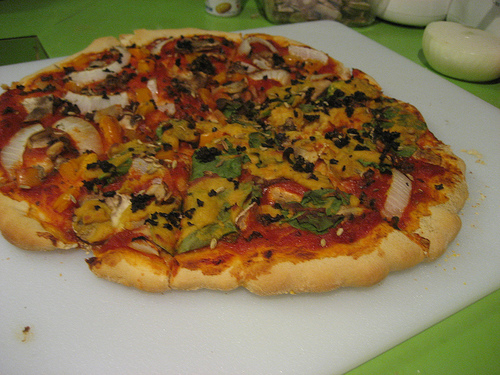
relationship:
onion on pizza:
[381, 167, 414, 222] [84, 49, 466, 316]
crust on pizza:
[83, 244, 175, 294] [5, 20, 465, 292]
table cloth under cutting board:
[0, 0, 500, 373] [0, 20, 500, 374]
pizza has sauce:
[5, 20, 465, 292] [92, 229, 163, 260]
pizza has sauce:
[5, 20, 465, 292] [324, 201, 381, 238]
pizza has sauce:
[5, 20, 465, 292] [36, 175, 63, 215]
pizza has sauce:
[5, 20, 465, 292] [238, 215, 295, 250]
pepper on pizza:
[433, 181, 445, 194] [5, 20, 465, 292]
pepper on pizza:
[345, 141, 380, 166] [5, 20, 465, 292]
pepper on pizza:
[161, 118, 196, 146] [5, 20, 465, 292]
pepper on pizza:
[107, 155, 137, 182] [5, 20, 465, 292]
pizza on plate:
[5, 20, 465, 292] [0, 19, 499, 373]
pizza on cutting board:
[5, 20, 465, 292] [0, 20, 500, 374]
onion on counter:
[419, 19, 499, 83] [0, 0, 499, 372]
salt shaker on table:
[203, 0, 243, 17] [1, 0, 498, 374]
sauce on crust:
[223, 221, 383, 246] [172, 262, 421, 298]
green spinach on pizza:
[193, 145, 252, 177] [5, 20, 465, 292]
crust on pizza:
[0, 156, 467, 298] [5, 20, 465, 292]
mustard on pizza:
[78, 103, 370, 248] [5, 20, 465, 292]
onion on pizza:
[381, 167, 414, 222] [21, 46, 497, 255]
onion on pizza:
[54, 116, 105, 155] [21, 46, 497, 255]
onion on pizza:
[3, 122, 43, 179] [21, 46, 497, 255]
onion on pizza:
[64, 91, 130, 114] [21, 46, 497, 255]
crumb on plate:
[21, 324, 31, 335] [0, 19, 499, 373]